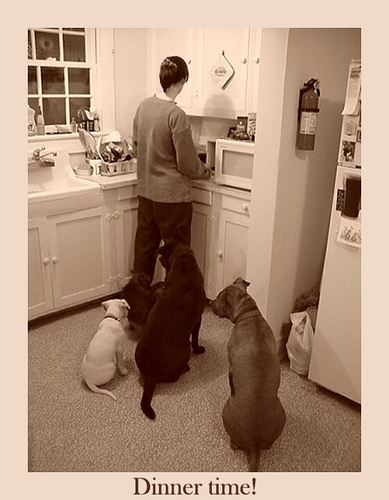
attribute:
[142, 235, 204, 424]
dog — large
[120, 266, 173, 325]
cat — waiting, adult age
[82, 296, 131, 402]
dog — small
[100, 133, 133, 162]
dishes — drying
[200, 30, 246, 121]
cabinet — white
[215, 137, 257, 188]
microwave — white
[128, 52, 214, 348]
woman — standing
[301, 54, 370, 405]
refrigerator — white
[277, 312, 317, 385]
bag — plastic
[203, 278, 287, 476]
dog — sitting, medium sized, tiny, brown, adult, adult age, waiting, large